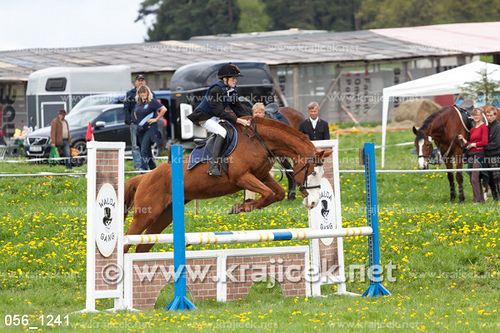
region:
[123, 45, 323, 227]
boy riding a brown horse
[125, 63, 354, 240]
boy riding a brown horse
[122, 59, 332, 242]
boy riding a brown horse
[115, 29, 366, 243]
boy riding a brown horse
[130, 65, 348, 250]
boy riding a brown horse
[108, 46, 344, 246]
boy riding a brown horse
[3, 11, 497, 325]
a scene outside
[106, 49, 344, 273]
a brown horse with a rider on it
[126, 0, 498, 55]
some trees in the background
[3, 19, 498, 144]
a building in the background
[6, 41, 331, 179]
some cars in the background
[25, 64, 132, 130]
A dark and medium gray horse trailer.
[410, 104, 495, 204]
A brown horse with a white blaze on its face.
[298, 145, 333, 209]
Chestnut colored horse with a mostly white face.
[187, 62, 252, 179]
A person on horseback wearing white pants.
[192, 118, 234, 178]
A black english saddle with black stirrups.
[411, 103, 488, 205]
A woman wearing a red shirt holding a brown horse.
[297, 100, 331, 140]
A man wearing a white shirt with a black jacket.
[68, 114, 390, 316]
A chestnut horse jumping a double jump.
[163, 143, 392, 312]
A blue, white and yellow horse jump.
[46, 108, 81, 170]
A man dressed in a brown jacket and blue jeans walking by a car.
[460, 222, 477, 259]
a yellow flower in a distance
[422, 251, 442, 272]
a yellow flower in a distance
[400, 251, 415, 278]
a yellow flower in a distance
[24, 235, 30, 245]
a yellow flower in a distance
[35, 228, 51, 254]
a yellow flower in a distance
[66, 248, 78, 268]
a yellow flower in a distance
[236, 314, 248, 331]
a yellow flower in a distance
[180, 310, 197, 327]
a yellow flower in a distance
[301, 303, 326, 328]
a yellow flower in a distance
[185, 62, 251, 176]
Kid on a horse wearing a black helmet and boots.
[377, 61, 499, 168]
A white tent.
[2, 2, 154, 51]
A white sky.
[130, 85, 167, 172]
Blonde woman standing with hands on her hips.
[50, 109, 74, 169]
Man walking in brown coat holding green sack.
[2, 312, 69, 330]
056_1241 in white.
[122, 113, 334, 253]
A brown horse jumping.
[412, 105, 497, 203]
A brown, black and white horse.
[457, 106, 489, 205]
A woman in a long sleeve red shirt and brown pants.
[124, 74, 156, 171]
A man standing in a black hat and jeans.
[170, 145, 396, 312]
the poles are blue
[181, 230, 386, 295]
bar between the poles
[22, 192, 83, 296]
the flowers are yellow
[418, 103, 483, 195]
the horse is standing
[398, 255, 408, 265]
small yellow flower by the horse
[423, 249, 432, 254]
small yellow flower by the horse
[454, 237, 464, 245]
small yellow flower by the horse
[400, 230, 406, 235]
small yellow flower by the horse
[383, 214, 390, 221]
small yellow flower by the horse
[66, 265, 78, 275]
small yellow flower by the horse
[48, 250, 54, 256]
small yellow flower by the horse